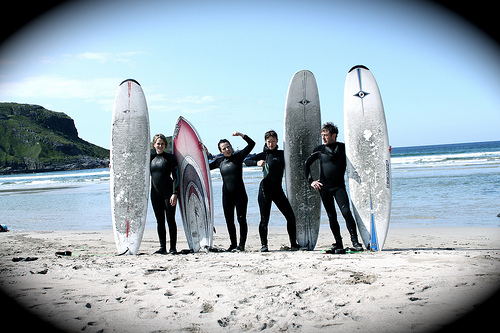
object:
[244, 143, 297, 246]
wet suit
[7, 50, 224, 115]
clouds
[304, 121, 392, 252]
person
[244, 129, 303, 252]
person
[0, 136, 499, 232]
water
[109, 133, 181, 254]
people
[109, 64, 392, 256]
surf boards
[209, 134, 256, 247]
wet suit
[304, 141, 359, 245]
wet suit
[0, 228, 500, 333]
beach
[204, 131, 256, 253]
person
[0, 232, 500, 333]
san pit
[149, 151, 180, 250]
wet suit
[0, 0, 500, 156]
sky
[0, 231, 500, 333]
sand